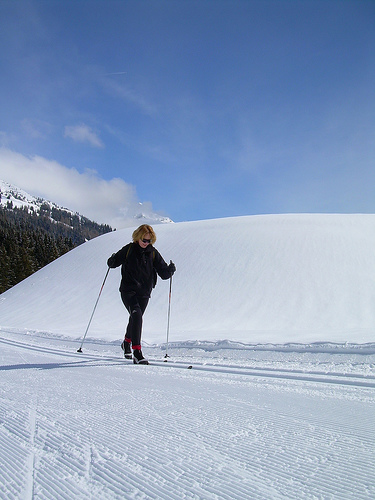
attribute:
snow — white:
[1, 325, 371, 497]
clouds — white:
[3, 144, 144, 223]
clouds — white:
[12, 137, 150, 224]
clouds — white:
[16, 160, 147, 229]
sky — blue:
[3, 2, 374, 212]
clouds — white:
[8, 102, 141, 149]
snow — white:
[1, 207, 370, 495]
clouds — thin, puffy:
[10, 139, 183, 231]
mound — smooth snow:
[4, 214, 372, 333]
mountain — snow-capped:
[1, 184, 117, 299]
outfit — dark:
[103, 240, 166, 353]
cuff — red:
[117, 332, 143, 351]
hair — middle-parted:
[130, 223, 157, 248]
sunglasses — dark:
[143, 239, 154, 243]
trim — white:
[126, 353, 153, 362]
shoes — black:
[121, 339, 148, 362]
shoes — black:
[120, 338, 150, 370]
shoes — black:
[118, 340, 152, 365]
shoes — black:
[117, 341, 146, 367]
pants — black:
[102, 296, 177, 354]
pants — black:
[97, 286, 178, 342]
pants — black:
[94, 276, 156, 331]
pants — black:
[90, 280, 177, 342]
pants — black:
[112, 290, 184, 360]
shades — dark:
[134, 237, 163, 247]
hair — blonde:
[124, 222, 168, 243]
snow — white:
[5, 176, 54, 212]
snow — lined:
[26, 345, 324, 478]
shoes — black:
[97, 335, 167, 373]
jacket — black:
[99, 246, 188, 316]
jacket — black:
[106, 244, 176, 286]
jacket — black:
[112, 233, 205, 316]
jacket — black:
[102, 246, 192, 299]